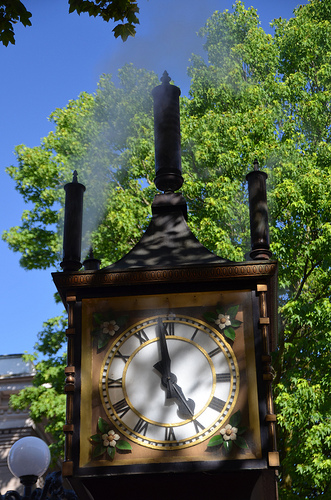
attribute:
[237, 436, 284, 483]
clock — black, square, telling time, fancy, gold trim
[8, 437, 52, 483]
bulb — round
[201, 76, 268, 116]
leaves — green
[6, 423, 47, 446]
light — bulb, circular, round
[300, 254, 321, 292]
branch — on tree, attached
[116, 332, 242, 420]
watch — a clock, white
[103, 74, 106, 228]
steam — blur, gray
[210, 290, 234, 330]
flowers — decorative, white, fancy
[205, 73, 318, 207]
tree — lively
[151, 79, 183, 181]
pole — black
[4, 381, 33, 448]
building — class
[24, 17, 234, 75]
sky — clear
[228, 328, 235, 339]
leaf — a flower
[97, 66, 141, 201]
smoke — gray